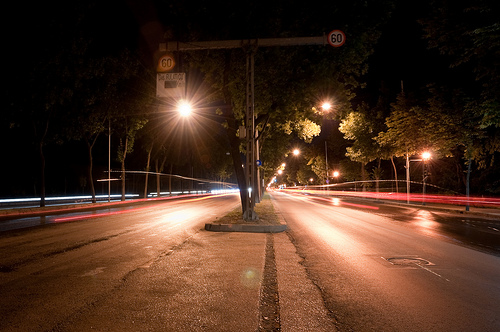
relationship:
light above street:
[315, 98, 337, 113] [284, 186, 490, 312]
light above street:
[172, 96, 196, 125] [50, 185, 211, 265]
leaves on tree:
[338, 112, 373, 141] [337, 109, 384, 190]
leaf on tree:
[309, 119, 313, 126] [259, 89, 336, 185]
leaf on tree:
[283, 119, 297, 126] [259, 89, 336, 185]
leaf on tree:
[298, 109, 299, 110] [259, 89, 336, 185]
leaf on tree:
[296, 113, 304, 120] [259, 89, 336, 185]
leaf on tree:
[305, 131, 309, 135] [259, 89, 336, 185]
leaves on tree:
[216, 67, 257, 114] [187, 74, 285, 191]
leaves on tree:
[7, 0, 124, 112] [67, 5, 158, 197]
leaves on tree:
[173, 5, 383, 143] [175, 0, 375, 219]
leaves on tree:
[413, 0, 496, 125] [380, 82, 495, 201]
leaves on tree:
[338, 101, 493, 153] [380, 82, 495, 201]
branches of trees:
[359, 159, 428, 203] [339, 107, 499, 207]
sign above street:
[157, 70, 187, 102] [42, 240, 100, 311]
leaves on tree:
[381, 112, 460, 139] [366, 98, 452, 196]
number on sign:
[328, 30, 344, 42] [317, 26, 350, 55]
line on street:
[413, 255, 449, 287] [269, 187, 496, 330]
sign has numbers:
[329, 32, 341, 48] [328, 30, 344, 42]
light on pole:
[315, 98, 334, 112] [317, 92, 349, 194]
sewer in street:
[377, 249, 437, 274] [0, 185, 498, 328]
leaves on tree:
[404, 108, 436, 128] [384, 55, 470, 183]